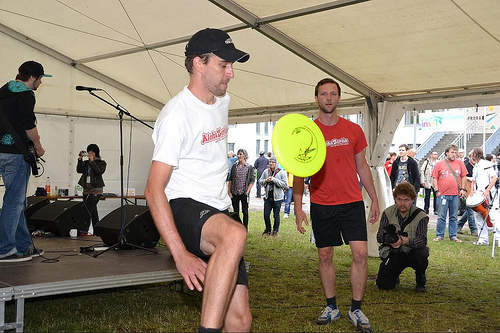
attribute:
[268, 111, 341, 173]
frisbee — yellow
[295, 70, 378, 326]
man — kneeling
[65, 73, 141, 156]
microphone — black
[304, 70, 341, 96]
hair — red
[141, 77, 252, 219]
shirt — white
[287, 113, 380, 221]
tshirt — red